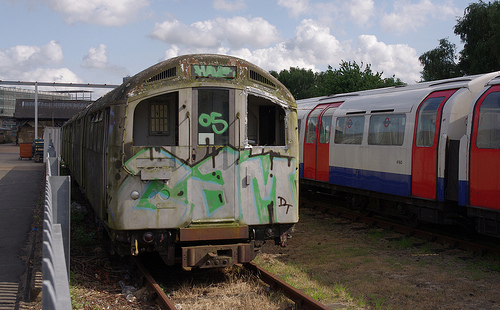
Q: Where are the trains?
A: On the tracks.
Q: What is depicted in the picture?
A: Two trains.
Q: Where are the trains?
A: On rail tracks.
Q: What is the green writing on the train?
A: Graffiti.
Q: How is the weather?
A: Grey and clear.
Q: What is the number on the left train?
A: 05.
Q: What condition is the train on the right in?
A: New.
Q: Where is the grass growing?
A: Between the trees.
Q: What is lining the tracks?
A: Metal fence.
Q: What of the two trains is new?
A: Red and blue.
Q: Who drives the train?
A: Pilot.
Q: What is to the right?
A: Train.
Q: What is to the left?
A: Rusted train.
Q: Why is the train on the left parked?
A: Old.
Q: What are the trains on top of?
A: Tracks.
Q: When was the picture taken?
A: Daytime.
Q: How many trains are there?
A: Two.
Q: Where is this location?
A: Train yard.